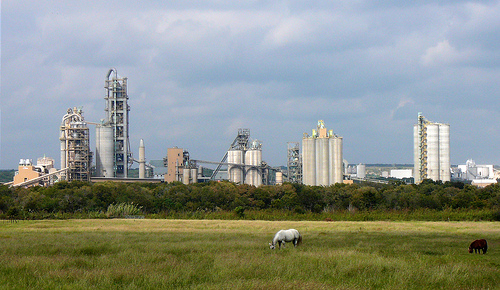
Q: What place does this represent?
A: It represents the field.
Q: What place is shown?
A: It is a field.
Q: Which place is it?
A: It is a field.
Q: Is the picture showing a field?
A: Yes, it is showing a field.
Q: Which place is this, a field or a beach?
A: It is a field.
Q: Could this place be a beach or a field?
A: It is a field.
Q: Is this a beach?
A: No, it is a field.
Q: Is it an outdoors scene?
A: Yes, it is outdoors.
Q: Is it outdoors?
A: Yes, it is outdoors.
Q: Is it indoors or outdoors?
A: It is outdoors.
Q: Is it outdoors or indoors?
A: It is outdoors.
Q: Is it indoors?
A: No, it is outdoors.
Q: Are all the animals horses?
A: Yes, all the animals are horses.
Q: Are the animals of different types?
A: No, all the animals are horses.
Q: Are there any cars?
A: No, there are no cars.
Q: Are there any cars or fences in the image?
A: No, there are no cars or fences.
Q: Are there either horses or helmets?
A: Yes, there is a horse.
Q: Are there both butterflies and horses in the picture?
A: No, there is a horse but no butterflies.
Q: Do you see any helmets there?
A: No, there are no helmets.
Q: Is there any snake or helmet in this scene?
A: No, there are no helmets or snakes.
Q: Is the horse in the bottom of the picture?
A: Yes, the horse is in the bottom of the image.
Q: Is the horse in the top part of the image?
A: No, the horse is in the bottom of the image.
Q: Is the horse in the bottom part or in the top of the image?
A: The horse is in the bottom of the image.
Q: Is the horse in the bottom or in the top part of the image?
A: The horse is in the bottom of the image.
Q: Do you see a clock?
A: No, there are no clocks.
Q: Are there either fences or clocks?
A: No, there are no clocks or fences.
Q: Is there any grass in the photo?
A: Yes, there is grass.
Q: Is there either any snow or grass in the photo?
A: Yes, there is grass.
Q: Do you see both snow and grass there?
A: No, there is grass but no snow.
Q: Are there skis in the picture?
A: No, there are no skis.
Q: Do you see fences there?
A: No, there are no fences.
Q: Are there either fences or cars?
A: No, there are no fences or cars.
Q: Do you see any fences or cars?
A: No, there are no fences or cars.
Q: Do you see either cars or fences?
A: No, there are no fences or cars.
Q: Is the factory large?
A: Yes, the factory is large.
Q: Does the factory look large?
A: Yes, the factory is large.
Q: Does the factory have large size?
A: Yes, the factory is large.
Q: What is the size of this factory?
A: The factory is large.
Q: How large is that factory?
A: The factory is large.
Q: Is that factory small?
A: No, the factory is large.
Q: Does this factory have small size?
A: No, the factory is large.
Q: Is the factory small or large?
A: The factory is large.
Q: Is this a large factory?
A: Yes, this is a large factory.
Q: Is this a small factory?
A: No, this is a large factory.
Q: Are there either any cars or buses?
A: No, there are no cars or buses.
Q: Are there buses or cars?
A: No, there are no cars or buses.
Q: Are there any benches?
A: No, there are no benches.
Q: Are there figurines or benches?
A: No, there are no benches or figurines.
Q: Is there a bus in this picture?
A: No, there are no buses.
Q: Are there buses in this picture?
A: No, there are no buses.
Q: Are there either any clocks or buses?
A: No, there are no buses or clocks.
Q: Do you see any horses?
A: Yes, there is a horse.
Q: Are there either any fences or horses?
A: Yes, there is a horse.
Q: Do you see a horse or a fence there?
A: Yes, there is a horse.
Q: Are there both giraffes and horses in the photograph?
A: No, there is a horse but no giraffes.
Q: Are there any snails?
A: No, there are no snails.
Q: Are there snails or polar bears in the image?
A: No, there are no snails or polar bears.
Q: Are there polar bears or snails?
A: No, there are no snails or polar bears.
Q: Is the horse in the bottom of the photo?
A: Yes, the horse is in the bottom of the image.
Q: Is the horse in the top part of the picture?
A: No, the horse is in the bottom of the image.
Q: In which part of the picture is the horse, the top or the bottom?
A: The horse is in the bottom of the image.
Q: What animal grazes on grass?
A: The horse grazes on grass.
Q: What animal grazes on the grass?
A: The horse grazes on grass.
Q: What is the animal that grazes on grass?
A: The animal is a horse.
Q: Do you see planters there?
A: No, there are no planters.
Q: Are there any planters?
A: No, there are no planters.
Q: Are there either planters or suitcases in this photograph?
A: No, there are no planters or suitcases.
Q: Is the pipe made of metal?
A: Yes, the pipe is made of metal.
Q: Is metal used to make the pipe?
A: Yes, the pipe is made of metal.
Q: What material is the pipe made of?
A: The pipe is made of metal.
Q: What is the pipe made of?
A: The pipe is made of metal.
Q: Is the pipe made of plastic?
A: No, the pipe is made of metal.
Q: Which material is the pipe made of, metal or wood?
A: The pipe is made of metal.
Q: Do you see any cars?
A: No, there are no cars.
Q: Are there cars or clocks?
A: No, there are no cars or clocks.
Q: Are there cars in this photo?
A: No, there are no cars.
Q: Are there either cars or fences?
A: No, there are no cars or fences.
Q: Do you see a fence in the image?
A: No, there are no fences.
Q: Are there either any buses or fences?
A: No, there are no fences or buses.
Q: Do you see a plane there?
A: No, there are no airplanes.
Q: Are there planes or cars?
A: No, there are no planes or cars.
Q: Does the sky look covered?
A: Yes, the sky is covered.